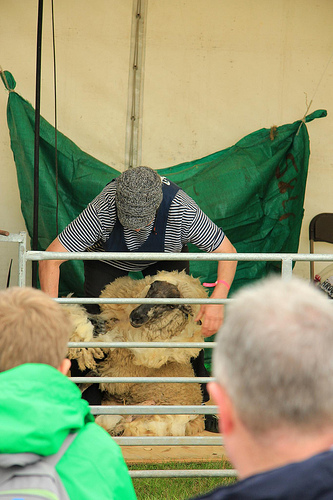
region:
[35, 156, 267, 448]
man sheering sheep in photo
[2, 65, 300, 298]
green tarp behind man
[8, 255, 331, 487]
two people watching man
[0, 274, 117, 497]
woman in green hoddie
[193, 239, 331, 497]
man with grey hair in blue shirt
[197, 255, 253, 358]
man wearing pink bracelet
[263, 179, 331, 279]
chair on side of photograph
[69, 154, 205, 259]
person wearing grey hat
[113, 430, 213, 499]
green grass visible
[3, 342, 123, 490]
person wearing grey backpack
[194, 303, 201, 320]
the finger of a person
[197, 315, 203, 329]
the finger of a person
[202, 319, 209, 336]
the finger of a person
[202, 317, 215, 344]
the finger of a person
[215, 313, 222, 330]
the ear of a person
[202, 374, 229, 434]
the ear of a person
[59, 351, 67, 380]
the ear of a person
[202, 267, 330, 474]
the head of a person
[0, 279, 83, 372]
the head of a person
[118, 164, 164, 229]
the head of a person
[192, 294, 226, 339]
the hand of a person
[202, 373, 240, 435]
the ear of a man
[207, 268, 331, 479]
the head of a man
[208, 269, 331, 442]
the gray hair of the man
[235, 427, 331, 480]
the neck of the man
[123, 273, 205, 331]
the head of a sheep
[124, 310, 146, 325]
the nose of the sheep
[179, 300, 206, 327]
the ear of the sheep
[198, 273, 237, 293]
a pink bracelet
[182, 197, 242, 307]
the arm of the person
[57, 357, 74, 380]
the ear of a person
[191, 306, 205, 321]
the ear of a person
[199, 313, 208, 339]
the ear of a person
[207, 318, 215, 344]
the ear of a person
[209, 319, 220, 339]
the ear of a person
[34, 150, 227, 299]
a person wearing a hat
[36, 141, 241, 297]
a person wearing a striped shirt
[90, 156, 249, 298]
a person wearing a pink bracelet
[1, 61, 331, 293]
a green tarp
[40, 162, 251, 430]
a person with a sheep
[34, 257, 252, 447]
a sheep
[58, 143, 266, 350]
a person wearing a blue vest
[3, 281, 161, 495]
a boy wearing a backpack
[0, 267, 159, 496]
a person wearing a green jacket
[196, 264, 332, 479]
a person with gray hair